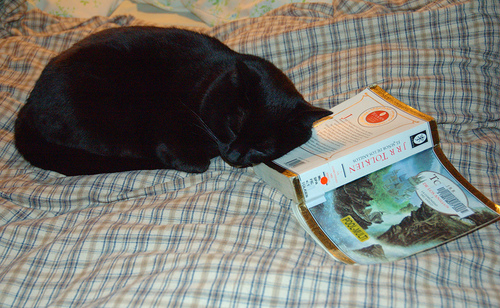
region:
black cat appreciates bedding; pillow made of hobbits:
[5, 22, 337, 179]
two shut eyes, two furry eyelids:
[220, 119, 270, 168]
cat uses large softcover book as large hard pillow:
[231, 78, 442, 207]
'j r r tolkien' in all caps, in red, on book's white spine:
[345, 138, 409, 180]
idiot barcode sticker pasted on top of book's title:
[410, 166, 477, 226]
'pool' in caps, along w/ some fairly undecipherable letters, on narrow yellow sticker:
[336, 208, 376, 245]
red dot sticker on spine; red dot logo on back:
[318, 173, 331, 186]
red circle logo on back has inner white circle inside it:
[375, 108, 388, 120]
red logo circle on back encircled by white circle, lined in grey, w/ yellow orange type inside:
[355, 101, 397, 129]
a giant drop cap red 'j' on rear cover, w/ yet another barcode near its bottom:
[281, 108, 354, 173]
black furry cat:
[8, 11, 336, 184]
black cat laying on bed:
[12, 17, 339, 187]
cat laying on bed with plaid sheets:
[2, 21, 342, 187]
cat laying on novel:
[20, 16, 337, 203]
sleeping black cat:
[15, 20, 337, 195]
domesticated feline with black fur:
[12, 14, 339, 193]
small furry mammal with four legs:
[8, 21, 338, 183]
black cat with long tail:
[8, 24, 343, 194]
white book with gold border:
[246, 66, 494, 267]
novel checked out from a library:
[250, 54, 498, 296]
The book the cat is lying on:
[255, 78, 499, 271]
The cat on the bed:
[8, 23, 332, 175]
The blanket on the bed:
[2, 1, 499, 306]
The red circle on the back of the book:
[363, 105, 391, 127]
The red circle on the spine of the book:
[318, 172, 329, 187]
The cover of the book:
[287, 148, 497, 265]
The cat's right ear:
[226, 50, 258, 98]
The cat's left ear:
[307, 103, 337, 128]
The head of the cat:
[196, 48, 333, 172]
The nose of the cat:
[215, 146, 251, 170]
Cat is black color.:
[8, 26, 321, 206]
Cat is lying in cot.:
[18, 33, 311, 193]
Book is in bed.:
[288, 71, 459, 263]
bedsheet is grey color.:
[57, 182, 277, 287]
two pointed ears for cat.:
[231, 46, 331, 126]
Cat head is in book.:
[212, 61, 329, 183]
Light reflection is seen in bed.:
[6, 2, 250, 61]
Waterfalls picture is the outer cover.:
[341, 162, 453, 267]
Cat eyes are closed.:
[224, 108, 285, 170]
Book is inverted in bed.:
[258, 108, 455, 269]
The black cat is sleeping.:
[20, 35, 310, 186]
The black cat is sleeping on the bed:
[27, 38, 301, 180]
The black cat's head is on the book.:
[198, 46, 313, 175]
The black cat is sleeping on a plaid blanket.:
[21, 20, 302, 182]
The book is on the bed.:
[286, 141, 489, 278]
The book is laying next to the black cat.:
[318, 120, 496, 267]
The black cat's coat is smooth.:
[21, 25, 268, 164]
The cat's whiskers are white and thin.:
[172, 105, 243, 157]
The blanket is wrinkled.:
[41, 191, 303, 304]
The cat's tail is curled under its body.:
[15, 70, 172, 209]